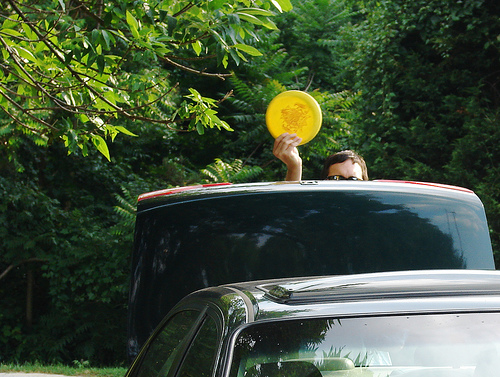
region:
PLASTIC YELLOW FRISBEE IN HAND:
[256, 81, 326, 146]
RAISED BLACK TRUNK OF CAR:
[107, 174, 496, 311]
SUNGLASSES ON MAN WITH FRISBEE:
[319, 166, 374, 188]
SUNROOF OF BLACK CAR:
[262, 274, 494, 296]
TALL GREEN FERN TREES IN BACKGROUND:
[8, 6, 429, 373]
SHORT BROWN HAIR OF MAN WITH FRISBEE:
[325, 143, 370, 166]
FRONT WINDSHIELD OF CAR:
[230, 310, 490, 370]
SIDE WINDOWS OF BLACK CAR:
[163, 290, 268, 375]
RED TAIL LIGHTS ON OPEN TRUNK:
[116, 171, 223, 201]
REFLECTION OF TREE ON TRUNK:
[244, 177, 495, 279]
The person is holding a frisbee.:
[213, 52, 326, 169]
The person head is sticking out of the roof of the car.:
[302, 150, 369, 210]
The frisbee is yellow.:
[247, 86, 319, 143]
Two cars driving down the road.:
[129, 164, 476, 351]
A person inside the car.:
[313, 149, 396, 235]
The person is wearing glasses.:
[321, 163, 364, 190]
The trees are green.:
[63, 34, 442, 157]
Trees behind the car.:
[66, 19, 480, 149]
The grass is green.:
[35, 340, 111, 375]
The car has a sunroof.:
[216, 141, 398, 200]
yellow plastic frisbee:
[269, 87, 326, 144]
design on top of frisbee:
[278, 97, 313, 133]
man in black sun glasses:
[317, 147, 381, 188]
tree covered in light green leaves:
[1, 3, 209, 157]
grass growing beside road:
[0, 357, 124, 373]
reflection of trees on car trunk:
[193, 203, 475, 268]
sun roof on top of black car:
[258, 260, 498, 305]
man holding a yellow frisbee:
[233, 77, 395, 196]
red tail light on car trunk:
[137, 154, 234, 215]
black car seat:
[246, 354, 326, 375]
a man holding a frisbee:
[266, 91, 370, 184]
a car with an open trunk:
[125, 177, 499, 375]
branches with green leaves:
[0, 0, 286, 148]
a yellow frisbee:
[266, 91, 323, 143]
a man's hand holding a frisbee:
[265, 91, 323, 181]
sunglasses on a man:
[329, 173, 364, 182]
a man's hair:
[326, 149, 363, 166]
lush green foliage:
[338, 3, 498, 147]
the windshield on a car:
[235, 310, 498, 375]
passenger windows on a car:
[122, 308, 224, 375]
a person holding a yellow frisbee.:
[255, 78, 398, 185]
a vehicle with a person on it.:
[123, 160, 494, 375]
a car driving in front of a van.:
[104, 275, 498, 372]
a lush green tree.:
[0, 0, 320, 147]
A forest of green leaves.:
[0, 139, 196, 372]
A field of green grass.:
[2, 356, 130, 374]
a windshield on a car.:
[230, 313, 497, 375]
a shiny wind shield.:
[129, 191, 486, 311]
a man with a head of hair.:
[316, 143, 374, 183]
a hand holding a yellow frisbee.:
[263, 124, 313, 183]